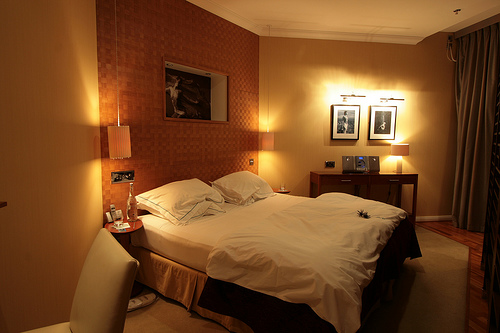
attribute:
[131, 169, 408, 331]
sheet — white 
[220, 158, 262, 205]
pillow — white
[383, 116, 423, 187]
light — on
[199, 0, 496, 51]
ceiling — white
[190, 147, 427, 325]
sheets — white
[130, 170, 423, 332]
bed — well spread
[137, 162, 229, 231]
pillow — white 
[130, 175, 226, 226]
pillow — white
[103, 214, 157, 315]
table — brown 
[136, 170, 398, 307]
sheet — white 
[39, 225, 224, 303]
seat — white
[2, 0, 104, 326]
wall — cream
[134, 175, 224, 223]
pillow — white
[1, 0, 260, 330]
wall — brown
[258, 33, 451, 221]
wall — brown